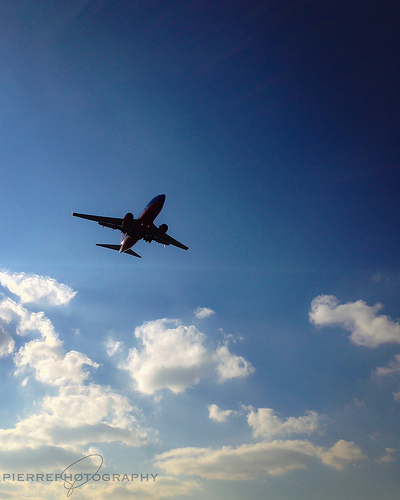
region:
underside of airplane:
[60, 181, 221, 287]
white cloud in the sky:
[36, 373, 160, 445]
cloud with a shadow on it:
[170, 442, 327, 483]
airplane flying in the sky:
[58, 162, 210, 293]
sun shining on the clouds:
[8, 268, 88, 359]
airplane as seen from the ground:
[52, 183, 253, 291]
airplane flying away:
[58, 190, 244, 280]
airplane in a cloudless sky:
[41, 167, 231, 265]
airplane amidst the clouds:
[58, 188, 256, 385]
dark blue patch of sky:
[211, 31, 335, 199]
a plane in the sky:
[68, 186, 192, 259]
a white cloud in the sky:
[201, 392, 329, 437]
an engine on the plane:
[117, 208, 133, 232]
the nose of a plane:
[156, 188, 165, 201]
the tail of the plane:
[92, 238, 144, 258]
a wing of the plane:
[70, 205, 138, 234]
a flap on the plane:
[94, 218, 124, 231]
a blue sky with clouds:
[0, 0, 399, 498]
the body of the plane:
[117, 191, 169, 253]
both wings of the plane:
[68, 206, 192, 252]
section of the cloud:
[359, 311, 375, 320]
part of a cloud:
[197, 364, 217, 373]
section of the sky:
[257, 369, 263, 377]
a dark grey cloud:
[174, 362, 182, 372]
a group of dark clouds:
[158, 430, 263, 473]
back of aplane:
[123, 239, 131, 252]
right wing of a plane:
[155, 233, 160, 243]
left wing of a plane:
[111, 218, 120, 223]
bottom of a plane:
[132, 228, 136, 240]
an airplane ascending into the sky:
[7, 46, 395, 476]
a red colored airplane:
[79, 181, 193, 281]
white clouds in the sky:
[0, 272, 399, 499]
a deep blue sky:
[1, 2, 398, 204]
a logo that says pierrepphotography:
[0, 462, 160, 499]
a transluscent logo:
[0, 455, 180, 499]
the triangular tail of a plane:
[89, 241, 146, 263]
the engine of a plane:
[120, 213, 134, 230]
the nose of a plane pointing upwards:
[134, 185, 183, 222]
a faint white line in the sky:
[0, 257, 384, 281]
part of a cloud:
[158, 352, 178, 380]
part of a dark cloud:
[200, 460, 221, 478]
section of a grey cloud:
[242, 441, 250, 454]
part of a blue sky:
[280, 369, 307, 373]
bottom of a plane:
[126, 238, 130, 244]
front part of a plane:
[158, 196, 165, 201]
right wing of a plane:
[114, 220, 124, 222]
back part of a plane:
[120, 242, 121, 244]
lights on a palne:
[144, 221, 152, 229]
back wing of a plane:
[111, 246, 116, 248]